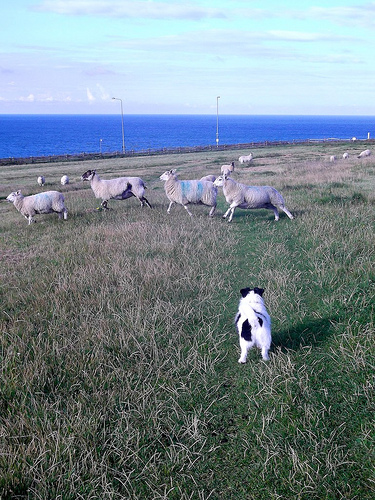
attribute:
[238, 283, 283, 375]
dog — black, white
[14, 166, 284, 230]
sheep — white, running, walking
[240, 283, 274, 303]
ears — black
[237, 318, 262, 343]
spot — black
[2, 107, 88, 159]
water — blue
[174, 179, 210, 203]
marks — blue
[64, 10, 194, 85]
sky — blue, cloudy, aqua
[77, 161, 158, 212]
sheep — running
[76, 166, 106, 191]
face — black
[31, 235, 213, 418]
grass — green, dead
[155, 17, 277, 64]
clouds — grey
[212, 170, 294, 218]
sheep — white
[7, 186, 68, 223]
sheep — white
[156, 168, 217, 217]
sheep — white